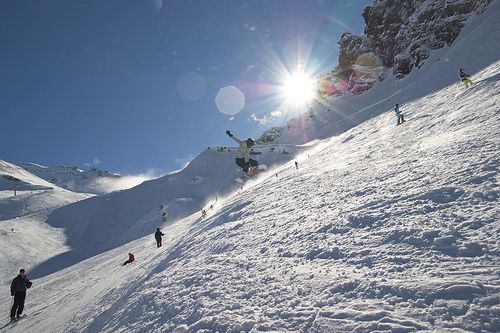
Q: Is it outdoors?
A: Yes, it is outdoors.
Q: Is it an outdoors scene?
A: Yes, it is outdoors.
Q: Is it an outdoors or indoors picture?
A: It is outdoors.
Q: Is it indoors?
A: No, it is outdoors.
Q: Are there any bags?
A: No, there are no bags.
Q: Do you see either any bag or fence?
A: No, there are no bags or fences.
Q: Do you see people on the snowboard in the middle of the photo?
A: Yes, there is a person on the snowboard.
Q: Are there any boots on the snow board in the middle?
A: No, there is a person on the snowboard.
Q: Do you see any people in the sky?
A: Yes, there is a person in the sky.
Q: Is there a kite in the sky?
A: No, there is a person in the sky.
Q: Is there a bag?
A: No, there are no bags.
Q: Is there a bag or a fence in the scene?
A: No, there are no bags or fences.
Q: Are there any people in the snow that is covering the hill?
A: Yes, there is a person in the snow.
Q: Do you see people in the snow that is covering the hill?
A: Yes, there is a person in the snow.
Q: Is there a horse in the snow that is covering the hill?
A: No, there is a person in the snow.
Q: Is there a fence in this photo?
A: No, there are no fences.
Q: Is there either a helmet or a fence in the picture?
A: No, there are no fences or helmets.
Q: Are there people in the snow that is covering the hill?
A: Yes, there is a person in the snow.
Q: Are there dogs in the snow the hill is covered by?
A: No, there is a person in the snow.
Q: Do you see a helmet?
A: No, there are no helmets.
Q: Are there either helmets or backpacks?
A: No, there are no helmets or backpacks.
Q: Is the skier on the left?
A: Yes, the skier is on the left of the image.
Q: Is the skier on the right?
A: No, the skier is on the left of the image.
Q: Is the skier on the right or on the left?
A: The skier is on the left of the image.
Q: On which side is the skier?
A: The skier is on the left of the image.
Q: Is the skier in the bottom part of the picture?
A: Yes, the skier is in the bottom of the image.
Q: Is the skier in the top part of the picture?
A: No, the skier is in the bottom of the image.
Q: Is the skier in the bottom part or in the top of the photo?
A: The skier is in the bottom of the image.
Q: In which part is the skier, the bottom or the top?
A: The skier is in the bottom of the image.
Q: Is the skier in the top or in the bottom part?
A: The skier is in the bottom of the image.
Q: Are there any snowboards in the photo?
A: Yes, there is a snowboard.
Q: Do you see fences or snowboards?
A: Yes, there is a snowboard.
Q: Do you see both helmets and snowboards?
A: No, there is a snowboard but no helmets.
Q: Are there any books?
A: No, there are no books.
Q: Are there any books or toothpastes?
A: No, there are no books or toothpastes.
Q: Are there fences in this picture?
A: No, there are no fences.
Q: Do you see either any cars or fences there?
A: No, there are no fences or cars.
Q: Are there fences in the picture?
A: No, there are no fences.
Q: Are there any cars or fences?
A: No, there are no fences or cars.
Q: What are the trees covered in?
A: The trees are covered in snow.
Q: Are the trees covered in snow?
A: Yes, the trees are covered in snow.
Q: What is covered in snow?
A: The trees are covered in snow.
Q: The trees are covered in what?
A: The trees are covered in snow.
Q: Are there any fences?
A: No, there are no fences.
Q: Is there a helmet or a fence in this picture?
A: No, there are no fences or helmets.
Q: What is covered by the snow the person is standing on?
A: The hill is covered by the snow.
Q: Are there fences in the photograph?
A: No, there are no fences.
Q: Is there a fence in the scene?
A: No, there are no fences.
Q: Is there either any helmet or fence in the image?
A: No, there are no fences or helmets.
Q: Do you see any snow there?
A: Yes, there is snow.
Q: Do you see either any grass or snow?
A: Yes, there is snow.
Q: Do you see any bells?
A: No, there are no bells.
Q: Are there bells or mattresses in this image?
A: No, there are no bells or mattresses.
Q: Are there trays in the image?
A: No, there are no trays.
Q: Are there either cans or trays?
A: No, there are no trays or cans.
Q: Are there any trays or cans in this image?
A: No, there are no trays or cans.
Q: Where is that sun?
A: The sun is in the sky.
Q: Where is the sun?
A: The sun is in the sky.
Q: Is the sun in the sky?
A: Yes, the sun is in the sky.